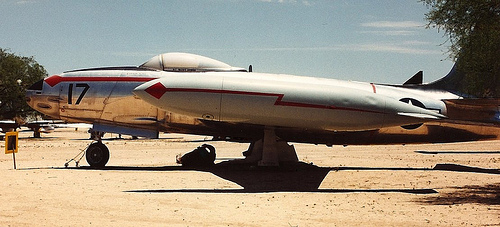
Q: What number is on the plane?
A: 17.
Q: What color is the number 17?
A: Black.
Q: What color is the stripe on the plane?
A: Red.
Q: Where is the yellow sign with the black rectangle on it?
A: Left hand side.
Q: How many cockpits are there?
A: One.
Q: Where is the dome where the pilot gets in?
A: On top of the plane.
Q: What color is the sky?
A: Blue.